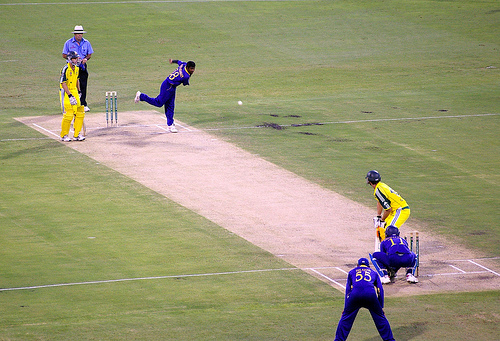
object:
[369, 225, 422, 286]
catcher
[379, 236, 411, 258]
blue jersey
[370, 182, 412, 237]
outfit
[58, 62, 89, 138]
outfit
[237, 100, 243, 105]
ball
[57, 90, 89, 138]
pants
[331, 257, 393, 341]
man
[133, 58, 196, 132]
man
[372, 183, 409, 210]
yellow jersey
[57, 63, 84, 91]
yellow jersey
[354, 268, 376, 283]
55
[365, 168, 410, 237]
baseball player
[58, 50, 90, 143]
baseball player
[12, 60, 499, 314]
ground